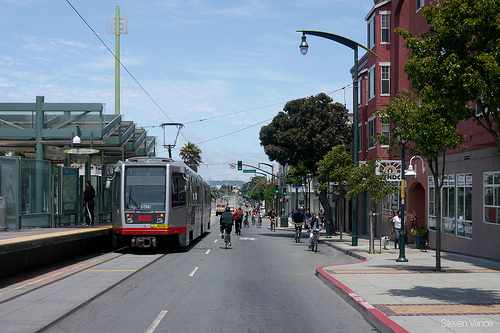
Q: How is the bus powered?
A: Electricity.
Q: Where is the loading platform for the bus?
A: On the left.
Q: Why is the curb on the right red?
A: No parking zone.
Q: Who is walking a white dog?
A: Person in white shirt.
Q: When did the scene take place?
A: Daytime.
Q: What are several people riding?
A: Bicycles.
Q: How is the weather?
A: Clear.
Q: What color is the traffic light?
A: Green.